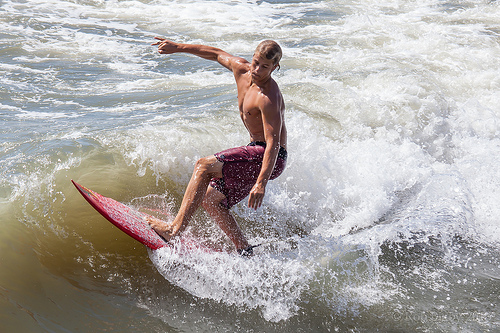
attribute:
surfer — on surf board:
[150, 50, 339, 258]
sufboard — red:
[58, 161, 205, 261]